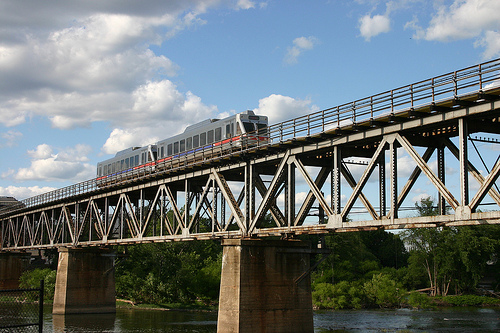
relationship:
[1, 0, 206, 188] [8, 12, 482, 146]
clouds in sky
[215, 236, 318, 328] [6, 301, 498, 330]
pillar in water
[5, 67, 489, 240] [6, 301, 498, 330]
bridge over water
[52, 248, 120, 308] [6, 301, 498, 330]
pillar in water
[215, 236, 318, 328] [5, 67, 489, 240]
pillar under bridge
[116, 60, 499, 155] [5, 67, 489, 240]
rail on bridge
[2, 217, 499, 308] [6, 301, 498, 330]
forest behind water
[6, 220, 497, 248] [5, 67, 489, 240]
bottom of bridge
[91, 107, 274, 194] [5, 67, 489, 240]
train over bridge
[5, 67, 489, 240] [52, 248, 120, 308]
bridge has pillar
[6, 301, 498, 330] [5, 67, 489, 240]
water under bridge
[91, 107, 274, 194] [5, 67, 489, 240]
train on bridge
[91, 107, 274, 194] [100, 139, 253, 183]
train has stripes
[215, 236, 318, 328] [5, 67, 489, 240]
pillar supports bridge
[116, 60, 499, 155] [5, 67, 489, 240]
rail beside bridge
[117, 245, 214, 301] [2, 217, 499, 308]
trees in forest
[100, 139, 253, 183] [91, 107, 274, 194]
stripes on train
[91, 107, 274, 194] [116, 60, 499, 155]
train cars on rail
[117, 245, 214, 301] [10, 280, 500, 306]
trees on bank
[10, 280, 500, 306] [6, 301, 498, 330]
bank by water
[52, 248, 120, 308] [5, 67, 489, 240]
pillar under bridge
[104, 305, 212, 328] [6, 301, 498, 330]
reflection on water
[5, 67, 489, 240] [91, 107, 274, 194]
bridge for train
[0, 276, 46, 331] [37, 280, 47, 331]
fence has pole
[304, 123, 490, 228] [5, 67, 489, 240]
beam on bridge